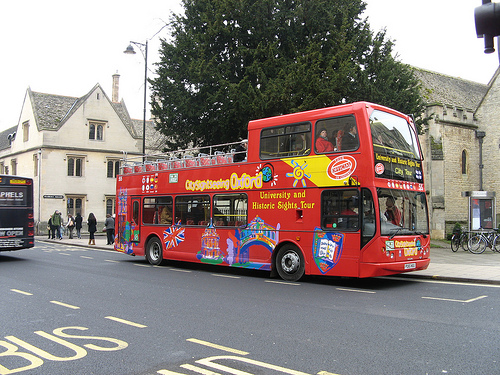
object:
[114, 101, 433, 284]
bus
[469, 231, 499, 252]
bicycle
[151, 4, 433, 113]
tree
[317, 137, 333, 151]
jacket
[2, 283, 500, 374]
street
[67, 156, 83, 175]
window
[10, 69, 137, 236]
building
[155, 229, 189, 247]
flag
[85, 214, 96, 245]
pedestrin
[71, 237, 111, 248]
sidewalk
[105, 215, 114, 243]
pedestrian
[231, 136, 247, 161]
passenger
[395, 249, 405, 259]
headlight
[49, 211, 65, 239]
person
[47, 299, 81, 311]
line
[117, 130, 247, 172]
top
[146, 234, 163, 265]
tire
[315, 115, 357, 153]
pane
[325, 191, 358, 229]
window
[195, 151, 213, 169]
seat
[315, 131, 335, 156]
passenger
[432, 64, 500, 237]
building